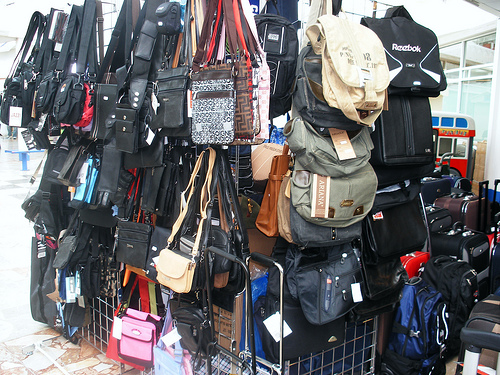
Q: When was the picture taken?
A: During the day.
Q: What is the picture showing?
A: A purse display.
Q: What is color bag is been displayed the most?
A: Black.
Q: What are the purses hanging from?
A: A rack tower.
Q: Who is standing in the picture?
A: No one.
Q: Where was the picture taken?
A: At a baggage store.